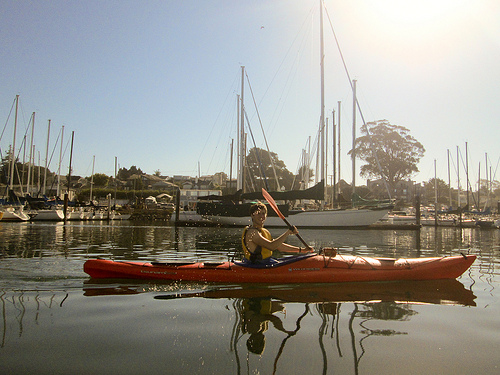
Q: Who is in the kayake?
A: A man.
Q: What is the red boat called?
A: Kayak.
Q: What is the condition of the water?
A: Calm.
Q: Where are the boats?
A: In the water.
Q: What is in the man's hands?
A: Paddle.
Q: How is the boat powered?
A: Man paddling.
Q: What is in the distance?
A: Buildings.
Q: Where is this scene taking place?
A: In the water.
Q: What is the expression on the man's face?
A: Smile.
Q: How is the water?
A: Clear.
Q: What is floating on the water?
A: A kayak.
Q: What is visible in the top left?
A: Bright sunlight.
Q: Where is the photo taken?
A: At the harbor.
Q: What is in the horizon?
A: Bright sunlight.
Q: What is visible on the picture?
A: A small splash of water.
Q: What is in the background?
A: Anchored boats.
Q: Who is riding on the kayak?
A: A person.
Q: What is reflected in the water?
A: The person on the kayak.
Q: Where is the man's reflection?
A: In the water.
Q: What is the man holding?
A: A paddle.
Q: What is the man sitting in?
A: A boat.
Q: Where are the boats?
A: On the water.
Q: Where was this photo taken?
A: By a harbor.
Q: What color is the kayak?
A: Orange.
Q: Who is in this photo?
A: A woman.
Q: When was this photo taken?
A: In the daytime.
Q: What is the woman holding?
A: An oar.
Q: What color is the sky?
A: Blue.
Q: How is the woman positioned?
A: By sitting.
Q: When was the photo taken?
A: Daytime.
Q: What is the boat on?
A: Water.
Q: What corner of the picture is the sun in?
A: Top right.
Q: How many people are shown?
A: One.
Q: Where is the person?
A: In the boat.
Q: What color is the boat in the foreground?
A: Red.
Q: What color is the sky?
A: Blue.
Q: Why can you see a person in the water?
A: Reflection.